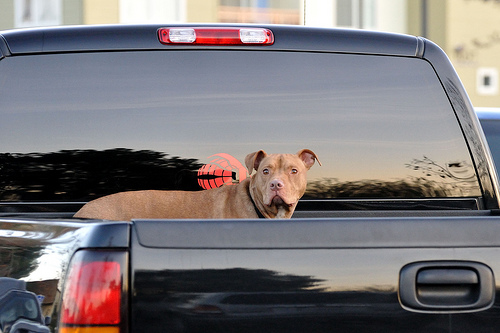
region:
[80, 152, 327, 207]
this is a dog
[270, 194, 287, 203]
this is the mouth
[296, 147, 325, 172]
this is an ear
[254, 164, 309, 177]
these are the eyes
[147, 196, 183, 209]
the fur is brown in color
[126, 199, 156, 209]
the fur is combed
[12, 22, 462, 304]
this is a car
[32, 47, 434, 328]
the car is big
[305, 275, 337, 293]
the car is black in color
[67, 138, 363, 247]
the dog is on the car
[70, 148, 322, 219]
Brown dog looking at camera.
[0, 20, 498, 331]
Brown dog is standing in bed of pickup truck.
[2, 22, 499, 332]
Black truck with dog in back.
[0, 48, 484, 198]
Red sticker on window.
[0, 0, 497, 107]
Buildings line the background.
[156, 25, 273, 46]
Red and white brake lights.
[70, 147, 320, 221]
Light brown dog with black collar.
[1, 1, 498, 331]
Dog is standing in back of black truck outside.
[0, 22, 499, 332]
Sticker on back window of truck.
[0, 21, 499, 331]
Red and white lights on roof of black truck.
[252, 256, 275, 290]
part of a shade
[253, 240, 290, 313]
part of a shade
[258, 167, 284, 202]
part of a niose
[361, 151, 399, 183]
part of a window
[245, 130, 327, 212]
head of a dog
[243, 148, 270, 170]
ear of a dog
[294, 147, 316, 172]
ear of a dog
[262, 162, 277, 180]
eye of a dog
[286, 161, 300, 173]
eye of a dog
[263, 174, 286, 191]
nose of a dog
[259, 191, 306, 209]
mouth of a dog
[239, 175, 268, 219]
neck of a dog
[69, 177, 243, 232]
body of a dog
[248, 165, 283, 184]
an eye of a dog